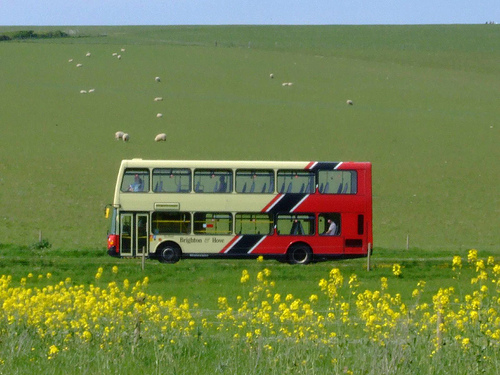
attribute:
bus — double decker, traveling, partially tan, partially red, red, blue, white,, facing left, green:
[97, 154, 378, 266]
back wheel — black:
[284, 239, 313, 268]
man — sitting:
[319, 216, 339, 238]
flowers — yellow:
[3, 243, 498, 374]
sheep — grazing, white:
[152, 130, 168, 144]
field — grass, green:
[0, 25, 499, 250]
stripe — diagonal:
[215, 157, 343, 258]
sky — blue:
[0, 0, 499, 27]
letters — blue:
[179, 235, 223, 246]